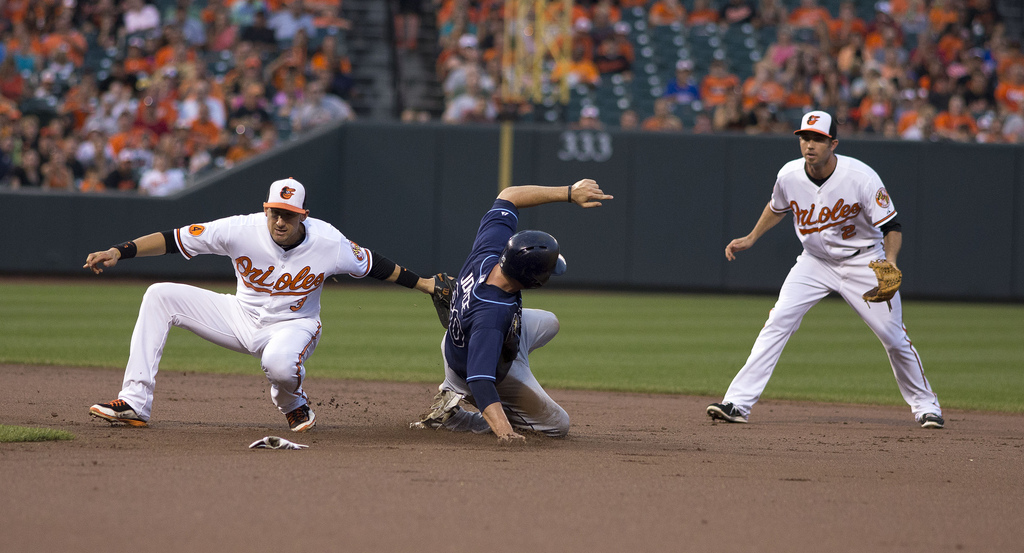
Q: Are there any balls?
A: No, there are no balls.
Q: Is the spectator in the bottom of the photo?
A: No, the spectator is in the top of the image.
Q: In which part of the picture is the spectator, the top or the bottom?
A: The spectator is in the top of the image.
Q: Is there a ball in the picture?
A: No, there are no balls.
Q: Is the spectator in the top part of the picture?
A: Yes, the spectator is in the top of the image.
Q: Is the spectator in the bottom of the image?
A: No, the spectator is in the top of the image.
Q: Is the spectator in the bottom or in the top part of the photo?
A: The spectator is in the top of the image.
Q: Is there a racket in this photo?
A: No, there are no rackets.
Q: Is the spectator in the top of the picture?
A: Yes, the spectator is in the top of the image.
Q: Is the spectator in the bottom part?
A: No, the spectator is in the top of the image.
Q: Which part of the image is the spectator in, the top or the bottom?
A: The spectator is in the top of the image.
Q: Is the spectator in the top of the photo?
A: Yes, the spectator is in the top of the image.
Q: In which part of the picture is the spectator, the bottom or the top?
A: The spectator is in the top of the image.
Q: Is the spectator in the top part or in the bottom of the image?
A: The spectator is in the top of the image.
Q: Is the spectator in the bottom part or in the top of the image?
A: The spectator is in the top of the image.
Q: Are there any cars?
A: No, there are no cars.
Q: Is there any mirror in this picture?
A: No, there are no mirrors.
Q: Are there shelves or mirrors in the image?
A: No, there are no mirrors or shelves.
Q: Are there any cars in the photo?
A: No, there are no cars.